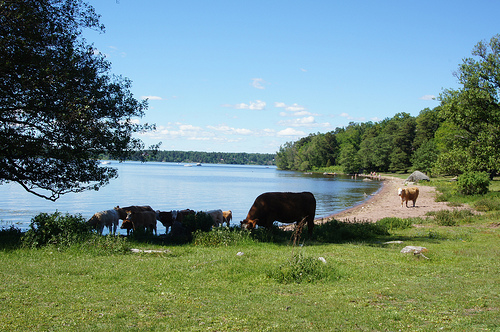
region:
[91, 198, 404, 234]
many cows standing together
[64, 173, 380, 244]
heard of cows by a lake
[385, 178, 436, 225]
cow standing in the dirt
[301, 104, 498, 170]
many green trees by a lake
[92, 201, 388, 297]
cows standing near the grass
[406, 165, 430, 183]
large grey rock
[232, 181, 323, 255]
brown cow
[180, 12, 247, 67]
white clouds in blue sky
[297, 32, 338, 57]
white clouds in blue sky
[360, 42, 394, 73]
white clouds in blue sky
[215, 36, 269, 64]
white clouds in blue sky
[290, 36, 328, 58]
white clouds in blue sky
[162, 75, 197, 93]
white clouds in blue sky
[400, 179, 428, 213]
cow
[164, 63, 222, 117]
white clouds in blue sky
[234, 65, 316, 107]
white clouds in blue sky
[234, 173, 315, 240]
brown cow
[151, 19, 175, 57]
white clouds in blue sky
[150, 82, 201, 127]
white clouds in blue sky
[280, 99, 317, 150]
white clouds in blue sky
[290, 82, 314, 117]
white clouds in blue sky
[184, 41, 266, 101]
white clouds in blue sky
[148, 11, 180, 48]
white clouds in blue sky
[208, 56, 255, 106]
white clouds in blue sky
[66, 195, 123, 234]
this is a cow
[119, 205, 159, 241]
this is a cow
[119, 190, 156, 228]
this is a cow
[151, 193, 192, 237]
this is a cow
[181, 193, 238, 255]
this is a cow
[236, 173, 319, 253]
this is a cow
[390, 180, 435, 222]
this is a cow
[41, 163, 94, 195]
this is a branch of a tree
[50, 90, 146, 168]
this is a branch of a tree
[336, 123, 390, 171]
this is a branch of a tree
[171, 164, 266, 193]
large body of water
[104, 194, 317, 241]
the animals are grazing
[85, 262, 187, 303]
the grass is short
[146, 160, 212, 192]
the water is calm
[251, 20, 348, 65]
the sky is clear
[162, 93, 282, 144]
the clouds are small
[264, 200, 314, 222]
the cow is dark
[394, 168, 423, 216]
cow on the sand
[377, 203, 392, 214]
the sand is tan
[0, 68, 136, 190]
the tree is dark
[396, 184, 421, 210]
Brown cow standing alone in the sand.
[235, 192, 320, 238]
Closest large brown cow in the shade.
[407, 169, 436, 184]
Rock behind a distant cow.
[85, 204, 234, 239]
Group of cows standing in the water.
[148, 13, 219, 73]
Large body of blue skies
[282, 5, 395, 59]
Large body of blue skies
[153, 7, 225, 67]
Large body of blue skies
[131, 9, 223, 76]
Large body of blue skies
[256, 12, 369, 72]
Large body of blue skies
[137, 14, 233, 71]
Large body of blue skies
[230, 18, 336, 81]
Large body of blue skies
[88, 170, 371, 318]
the cattle are grazing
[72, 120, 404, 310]
this is a lake front